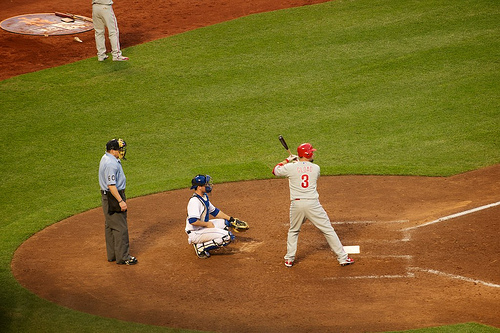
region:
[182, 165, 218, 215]
blue and black helmet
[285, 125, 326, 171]
red and white helmet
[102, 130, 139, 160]
black and gold helmet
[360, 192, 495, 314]
white chalk lines on field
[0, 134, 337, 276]
three people playing baseball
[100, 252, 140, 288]
black and white cleats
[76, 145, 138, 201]
man wearing a blue shirt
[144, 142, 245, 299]
man squatting down on field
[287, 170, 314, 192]
number 3 on a jersey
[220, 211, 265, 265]
brown and black base ball glave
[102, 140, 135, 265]
umpire standing behind catcher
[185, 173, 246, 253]
catcher squatting behind batter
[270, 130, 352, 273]
batter ready to swing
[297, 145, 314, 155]
red helmet on batter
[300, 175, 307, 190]
red number 3 on gray jersey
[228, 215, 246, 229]
black and yellow baseball glove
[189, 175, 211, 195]
blue catcher's helmet and facemask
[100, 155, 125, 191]
blue umpire shirt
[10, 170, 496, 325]
brown dirt on baseball field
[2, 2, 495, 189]
green grass on baseball field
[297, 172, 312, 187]
The number 3 on the back of the batter's shirt.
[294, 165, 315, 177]
The name on the back of the batter's shirt.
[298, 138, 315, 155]
The red helmet the batter is wearing.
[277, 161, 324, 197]
The uniform shirt of the batter.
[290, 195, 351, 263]
The gray pants the batter is wearing.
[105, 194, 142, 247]
The gray pants the umpire is wearing.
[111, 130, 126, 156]
The face guard shield the umpire is wearing.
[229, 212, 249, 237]
The glove on the catcher's hand.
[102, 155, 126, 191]
The blue shirt the umpire is wearing.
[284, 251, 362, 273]
The red sneakers the batter is wearing.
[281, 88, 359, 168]
the helmet is red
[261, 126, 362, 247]
the helmet is red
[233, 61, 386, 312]
the helmet is red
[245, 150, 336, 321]
the helmet is red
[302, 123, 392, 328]
the helmet is red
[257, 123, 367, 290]
a batter standing in position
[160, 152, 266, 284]
a catcher kneeling in the dirt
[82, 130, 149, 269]
umpire watching the batter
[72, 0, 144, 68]
person standing on the sidelines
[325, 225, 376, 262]
white home base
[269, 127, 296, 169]
a wooden baseball bat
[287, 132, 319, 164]
red baseball helmet on the batter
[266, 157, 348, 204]
a gray and red baseball uniform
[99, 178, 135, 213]
a black apron around the umpire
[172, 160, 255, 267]
a white and blue baseball uniform